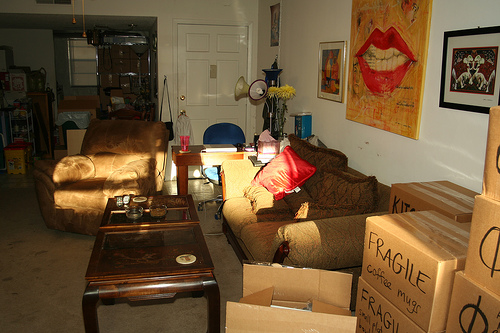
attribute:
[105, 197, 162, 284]
table — brown, wooden, big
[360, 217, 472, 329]
boxes — brown, cardboard, closed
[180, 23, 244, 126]
door — closed, white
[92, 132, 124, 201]
chair — brown, suede, recliner, big, reclined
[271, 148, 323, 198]
pillow — red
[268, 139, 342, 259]
couch — brown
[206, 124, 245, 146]
chair — blue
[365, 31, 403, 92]
lips — red, big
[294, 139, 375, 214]
pillows — brown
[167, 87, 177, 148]
purse — black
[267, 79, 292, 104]
flowers — yellow, tall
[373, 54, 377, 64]
teeth — white, big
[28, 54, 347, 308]
room — messy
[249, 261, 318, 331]
box — opened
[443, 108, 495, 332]
boxes — stacked